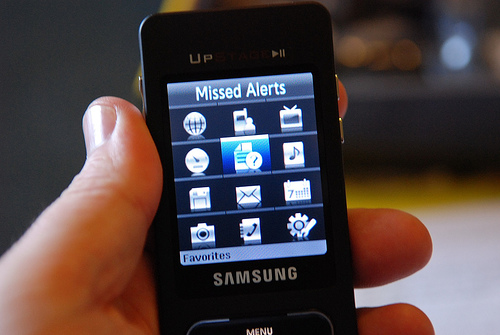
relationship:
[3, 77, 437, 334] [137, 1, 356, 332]
hand holding cellphone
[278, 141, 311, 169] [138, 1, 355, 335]
music on cellphone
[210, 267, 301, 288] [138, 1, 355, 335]
brand on front of cellphone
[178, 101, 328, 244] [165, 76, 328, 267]
apps on phone screen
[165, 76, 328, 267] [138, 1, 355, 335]
phone screen on cellphone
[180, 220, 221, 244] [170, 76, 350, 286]
camera icon on phone screen